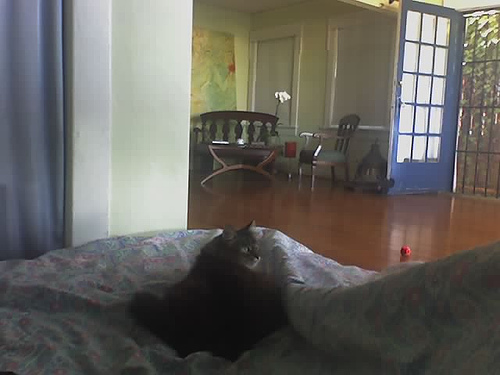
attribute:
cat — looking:
[149, 219, 301, 356]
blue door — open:
[379, 2, 458, 200]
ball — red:
[375, 229, 423, 264]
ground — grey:
[345, 165, 385, 244]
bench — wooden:
[193, 105, 285, 194]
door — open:
[384, 0, 469, 200]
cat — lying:
[129, 218, 290, 367]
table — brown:
[202, 142, 287, 188]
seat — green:
[300, 148, 347, 160]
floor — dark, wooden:
[182, 151, 497, 282]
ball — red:
[392, 245, 426, 259]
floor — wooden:
[306, 193, 386, 246]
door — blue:
[392, 2, 469, 241]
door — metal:
[387, 0, 499, 199]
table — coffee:
[193, 104, 275, 191]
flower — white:
[270, 88, 294, 110]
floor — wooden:
[192, 158, 499, 276]